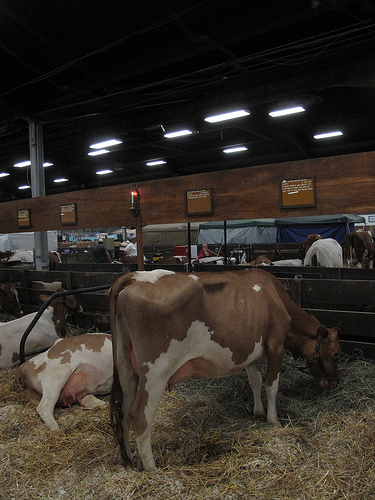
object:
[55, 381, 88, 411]
udder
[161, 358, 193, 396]
udder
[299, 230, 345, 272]
cow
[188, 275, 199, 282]
spot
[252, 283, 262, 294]
spot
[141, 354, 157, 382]
spot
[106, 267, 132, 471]
tail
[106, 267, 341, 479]
cow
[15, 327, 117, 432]
cow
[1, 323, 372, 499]
hay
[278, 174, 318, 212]
sign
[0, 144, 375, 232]
wall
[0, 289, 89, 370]
cow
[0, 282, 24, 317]
cow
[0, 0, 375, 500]
stall